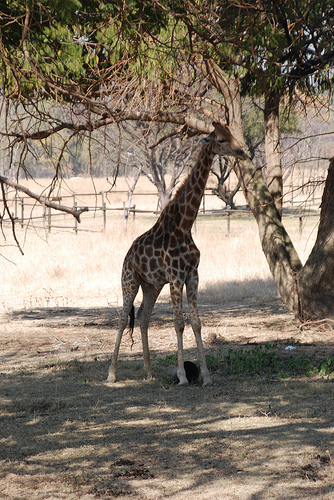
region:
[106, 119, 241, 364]
Giraffee is looking at camera and in the shade of a tree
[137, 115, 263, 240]
Giraffee is eating under a tree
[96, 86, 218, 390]
The giraffe has white feet above it's hoofs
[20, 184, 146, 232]
There is a brown rickety old fence in background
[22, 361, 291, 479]
A shadow of the trees appears on the ground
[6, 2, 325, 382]
A giraffee is standing under a huge tree with lots of leaves and a fence in the background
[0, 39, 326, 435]
A huge tree stands in a field with a giraffee underneath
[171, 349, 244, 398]
A food dish underneath a giraffee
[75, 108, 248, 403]
A brown and white giraffe stands on a patch of dead grass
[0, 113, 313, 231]
An old wooden gate keeps the giraffe from getting out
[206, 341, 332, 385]
Green grass on ground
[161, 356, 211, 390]
Black bucket on ground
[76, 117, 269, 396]
A giraffe standing in the shade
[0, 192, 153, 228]
A wooden fence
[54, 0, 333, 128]
Trees with green leaves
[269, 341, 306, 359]
Piece of white paper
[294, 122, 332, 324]
A brown tree trunk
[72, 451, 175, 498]
Giraffe droppings on ground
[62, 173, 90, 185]
A large rock in a field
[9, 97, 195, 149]
Trees with dead limbs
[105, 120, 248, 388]
giraffe standing in field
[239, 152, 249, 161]
giraffe has a mouth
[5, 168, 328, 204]
field behind post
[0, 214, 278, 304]
grass behind giraffe is dry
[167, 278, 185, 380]
giraffe has long legs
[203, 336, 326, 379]
green area by giraffe's feet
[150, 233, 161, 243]
brown spot on giraffe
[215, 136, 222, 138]
eye on giraffe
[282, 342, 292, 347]
small white object on ground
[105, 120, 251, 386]
giraffe is brown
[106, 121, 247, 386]
giraffe standing next to tree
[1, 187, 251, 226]
brown wooden fence behind giraffe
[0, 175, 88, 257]
dry branch to the left of the giraffe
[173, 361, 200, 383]
bucket near giraffe's leg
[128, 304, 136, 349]
giraffe has a dark tail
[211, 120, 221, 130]
horn on giraffes head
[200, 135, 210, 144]
ear on giraffe's head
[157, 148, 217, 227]
giraffe has along neck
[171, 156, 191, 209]
short mane on the back of giraffe's neck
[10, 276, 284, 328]
tree casts shadow behind giraffe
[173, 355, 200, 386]
Black flower pot in between giraffe's hooves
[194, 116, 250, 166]
Giraffe's head facing right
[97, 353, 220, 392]
Four giraffe hooves on the ground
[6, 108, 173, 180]
Limbs with no leaves on a tree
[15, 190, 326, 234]
Wooden fence behind giraffe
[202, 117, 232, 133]
Giraffe horns on top of head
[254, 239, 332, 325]
Split in a tree trunk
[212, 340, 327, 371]
Patch of green on a dirt ground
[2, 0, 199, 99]
Tree with green leaves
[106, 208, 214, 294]
Spots on a giraffe's body